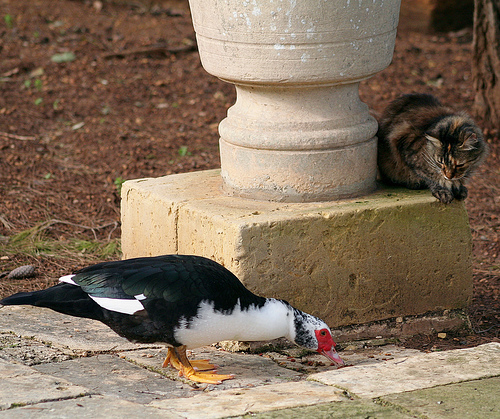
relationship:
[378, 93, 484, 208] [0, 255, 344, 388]
cat looking at duck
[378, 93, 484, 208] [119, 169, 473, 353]
cat on top of block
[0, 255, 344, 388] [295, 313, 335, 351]
duck has head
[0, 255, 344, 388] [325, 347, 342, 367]
duck has beak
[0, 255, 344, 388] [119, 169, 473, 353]
duck next to block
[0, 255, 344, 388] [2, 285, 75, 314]
duck has tail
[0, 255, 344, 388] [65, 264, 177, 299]
duck has wings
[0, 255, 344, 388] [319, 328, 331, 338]
duck has right eye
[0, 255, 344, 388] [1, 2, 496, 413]
duck on top of ground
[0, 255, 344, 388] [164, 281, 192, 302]
duck has feather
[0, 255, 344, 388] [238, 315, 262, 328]
duck has feather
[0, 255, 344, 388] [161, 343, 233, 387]
duck has feet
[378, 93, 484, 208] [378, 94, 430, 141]
cat has stripes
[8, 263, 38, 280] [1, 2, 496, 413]
pine cone on ground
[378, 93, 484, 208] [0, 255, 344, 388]
cat watching duck